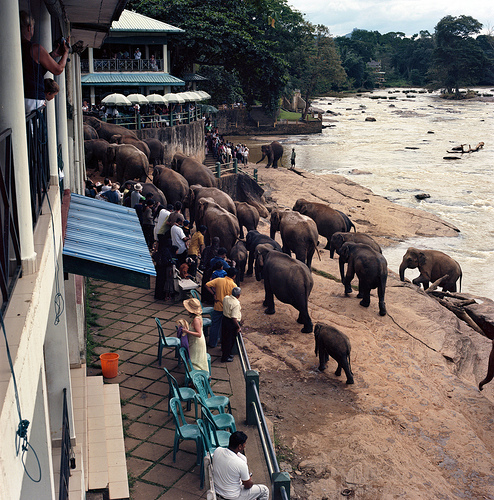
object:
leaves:
[188, 0, 317, 105]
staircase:
[198, 112, 255, 168]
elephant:
[314, 321, 355, 385]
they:
[100, 183, 120, 204]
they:
[142, 199, 155, 251]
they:
[171, 214, 192, 265]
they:
[221, 286, 242, 362]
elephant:
[254, 243, 314, 334]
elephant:
[229, 241, 248, 288]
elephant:
[292, 198, 347, 250]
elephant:
[198, 197, 247, 253]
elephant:
[171, 151, 217, 187]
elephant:
[152, 165, 190, 207]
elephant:
[120, 180, 167, 208]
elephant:
[111, 134, 151, 160]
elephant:
[141, 138, 164, 168]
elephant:
[86, 117, 139, 143]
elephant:
[83, 122, 99, 169]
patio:
[82, 264, 276, 500]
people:
[85, 180, 242, 379]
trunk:
[399, 262, 407, 281]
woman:
[177, 298, 211, 381]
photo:
[0, 0, 494, 500]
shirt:
[223, 295, 241, 322]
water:
[213, 86, 492, 317]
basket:
[100, 353, 120, 379]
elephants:
[82, 116, 462, 384]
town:
[0, 0, 294, 497]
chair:
[163, 366, 199, 425]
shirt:
[211, 446, 251, 499]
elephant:
[256, 141, 284, 169]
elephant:
[234, 201, 260, 239]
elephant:
[105, 143, 152, 185]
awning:
[63, 192, 158, 290]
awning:
[81, 72, 186, 86]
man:
[208, 430, 270, 499]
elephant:
[399, 245, 462, 293]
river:
[281, 85, 493, 303]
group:
[101, 90, 211, 105]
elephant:
[270, 208, 321, 274]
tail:
[309, 230, 321, 261]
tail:
[459, 268, 462, 293]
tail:
[348, 349, 355, 376]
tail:
[349, 220, 356, 233]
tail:
[141, 155, 152, 181]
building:
[0, 0, 158, 500]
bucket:
[99, 352, 120, 378]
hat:
[183, 298, 203, 315]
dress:
[187, 315, 210, 380]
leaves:
[360, 61, 372, 90]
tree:
[360, 70, 374, 89]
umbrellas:
[189, 90, 211, 101]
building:
[79, 6, 205, 165]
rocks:
[176, 166, 492, 498]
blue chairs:
[155, 317, 182, 369]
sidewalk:
[86, 278, 273, 500]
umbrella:
[101, 93, 132, 107]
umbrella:
[126, 93, 149, 104]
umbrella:
[145, 93, 168, 103]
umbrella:
[163, 93, 186, 103]